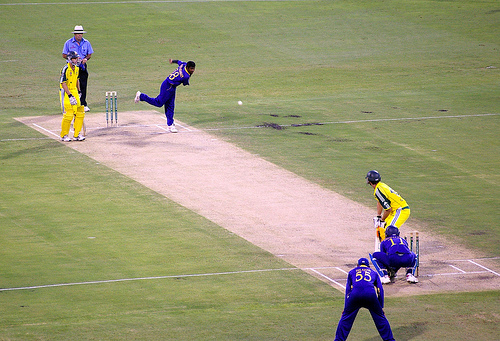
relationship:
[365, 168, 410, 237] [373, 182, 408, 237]
baseball player in outfit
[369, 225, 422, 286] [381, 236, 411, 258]
catcher in blue jersey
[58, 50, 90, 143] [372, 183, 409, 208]
baseball player has yellow jersey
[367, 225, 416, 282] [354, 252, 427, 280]
catcher behind plate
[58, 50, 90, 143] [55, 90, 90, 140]
baseball player wearing pants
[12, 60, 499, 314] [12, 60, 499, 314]
ground on ground